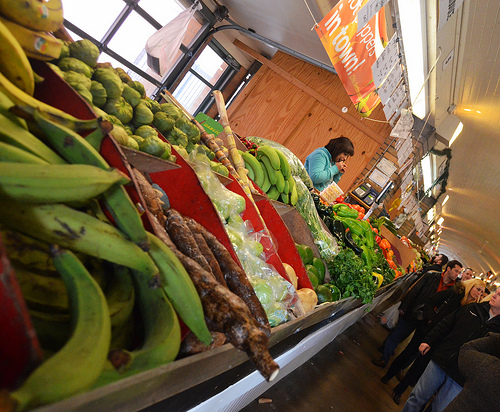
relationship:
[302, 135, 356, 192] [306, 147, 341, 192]
woman wearing top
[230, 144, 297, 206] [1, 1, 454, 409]
fruit being sold at a farmers market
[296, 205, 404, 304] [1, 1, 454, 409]
vegetables being sold at a farmers market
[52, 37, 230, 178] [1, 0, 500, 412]
fruit in a farmers market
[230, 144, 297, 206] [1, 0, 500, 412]
fruit in a farmers market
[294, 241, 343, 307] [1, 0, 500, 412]
fruit in a farmers market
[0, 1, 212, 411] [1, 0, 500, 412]
fruit in a farmers market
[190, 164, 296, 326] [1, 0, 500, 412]
fruit in a farmers market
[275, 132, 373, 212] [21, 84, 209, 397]
woman behind food